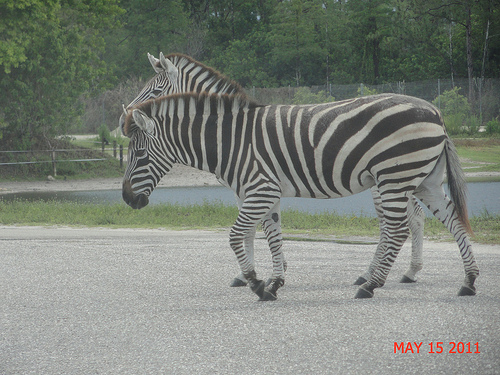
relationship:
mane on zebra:
[122, 92, 260, 137] [122, 93, 478, 300]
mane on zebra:
[151, 47, 246, 94] [118, 49, 478, 301]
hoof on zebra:
[251, 279, 266, 296] [122, 93, 478, 300]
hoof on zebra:
[353, 286, 374, 298] [122, 93, 478, 300]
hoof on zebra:
[456, 285, 475, 296] [122, 93, 478, 300]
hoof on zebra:
[228, 276, 247, 288] [118, 49, 478, 301]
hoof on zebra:
[258, 291, 277, 300] [122, 93, 478, 300]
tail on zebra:
[442, 130, 478, 243] [122, 93, 478, 300]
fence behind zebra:
[242, 79, 498, 146] [122, 93, 478, 300]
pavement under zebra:
[1, 224, 499, 371] [122, 93, 478, 300]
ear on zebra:
[160, 51, 178, 80] [118, 49, 478, 301]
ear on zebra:
[146, 51, 161, 79] [118, 49, 478, 301]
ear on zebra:
[132, 107, 153, 134] [122, 93, 478, 300]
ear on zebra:
[121, 101, 128, 117] [122, 93, 478, 300]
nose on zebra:
[119, 181, 150, 210] [122, 93, 478, 300]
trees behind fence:
[0, 1, 498, 168] [242, 79, 498, 146]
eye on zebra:
[135, 147, 149, 158] [122, 93, 478, 300]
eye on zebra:
[149, 88, 161, 97] [118, 49, 478, 301]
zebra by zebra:
[122, 93, 478, 300] [118, 49, 478, 301]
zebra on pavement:
[122, 93, 478, 300] [1, 224, 499, 371]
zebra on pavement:
[118, 49, 478, 301] [1, 224, 499, 371]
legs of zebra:
[230, 193, 284, 306] [122, 93, 478, 300]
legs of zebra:
[357, 165, 480, 300] [122, 93, 478, 300]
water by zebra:
[1, 179, 498, 221] [122, 93, 478, 300]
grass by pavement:
[0, 197, 499, 239] [1, 224, 499, 371]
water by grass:
[1, 179, 498, 221] [0, 197, 499, 239]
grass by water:
[0, 197, 499, 239] [1, 179, 498, 221]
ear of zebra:
[146, 51, 161, 79] [118, 49, 478, 301]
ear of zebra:
[160, 51, 178, 80] [118, 49, 478, 301]